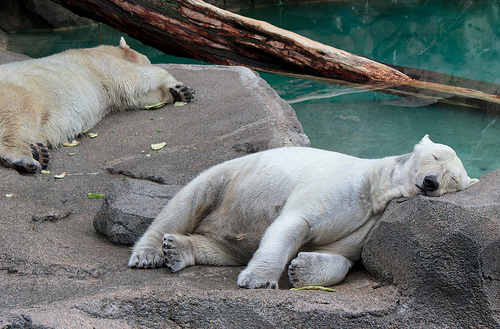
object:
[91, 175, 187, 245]
rock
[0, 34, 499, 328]
ground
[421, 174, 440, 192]
nose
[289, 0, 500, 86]
reflection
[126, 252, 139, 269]
toes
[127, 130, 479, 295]
bear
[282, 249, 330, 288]
paw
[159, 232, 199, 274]
paw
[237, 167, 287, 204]
fur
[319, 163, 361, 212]
skin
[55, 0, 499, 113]
log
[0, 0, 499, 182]
under water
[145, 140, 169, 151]
rind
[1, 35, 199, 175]
bear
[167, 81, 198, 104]
black paws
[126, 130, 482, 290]
nap